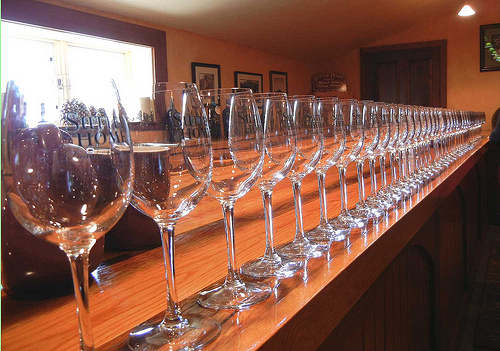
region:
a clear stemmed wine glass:
[4, 72, 127, 344]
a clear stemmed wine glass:
[115, 79, 218, 347]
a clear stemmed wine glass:
[181, 85, 272, 311]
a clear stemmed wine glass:
[223, 86, 300, 281]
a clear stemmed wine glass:
[262, 90, 322, 261]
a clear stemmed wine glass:
[293, 90, 346, 245]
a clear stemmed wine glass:
[318, 94, 368, 232]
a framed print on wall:
[188, 58, 223, 109]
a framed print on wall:
[231, 67, 263, 109]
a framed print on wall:
[266, 69, 289, 101]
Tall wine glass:
[5, 71, 127, 349]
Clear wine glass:
[113, 72, 215, 349]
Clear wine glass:
[189, 76, 267, 336]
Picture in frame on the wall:
[475, 22, 498, 77]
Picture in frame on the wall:
[185, 55, 225, 121]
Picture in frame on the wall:
[230, 70, 265, 109]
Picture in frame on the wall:
[269, 70, 290, 112]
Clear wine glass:
[283, 96, 321, 256]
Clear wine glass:
[362, 98, 382, 237]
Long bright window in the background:
[0, 45, 170, 122]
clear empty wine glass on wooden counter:
[4, 67, 131, 341]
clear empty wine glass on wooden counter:
[131, 88, 206, 340]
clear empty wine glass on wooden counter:
[203, 87, 265, 209]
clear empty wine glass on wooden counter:
[285, 94, 327, 260]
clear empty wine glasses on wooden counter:
[353, 104, 380, 225]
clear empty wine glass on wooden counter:
[395, 103, 419, 200]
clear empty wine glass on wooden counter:
[453, 112, 465, 157]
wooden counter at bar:
[335, 279, 467, 340]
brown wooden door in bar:
[358, 40, 447, 96]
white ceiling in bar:
[186, 9, 391, 31]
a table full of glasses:
[10, 10, 499, 307]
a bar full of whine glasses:
[44, 10, 498, 246]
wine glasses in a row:
[11, 17, 493, 284]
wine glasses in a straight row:
[19, 17, 495, 327]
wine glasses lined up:
[34, 45, 494, 277]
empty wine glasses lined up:
[11, 20, 478, 315]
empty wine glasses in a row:
[39, 17, 484, 303]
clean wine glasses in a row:
[1, 25, 404, 348]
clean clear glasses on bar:
[32, 37, 499, 309]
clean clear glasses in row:
[18, 28, 496, 303]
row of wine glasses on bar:
[129, 103, 463, 201]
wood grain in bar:
[105, 276, 148, 313]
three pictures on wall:
[177, 56, 298, 108]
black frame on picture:
[163, 50, 228, 97]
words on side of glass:
[54, 108, 128, 154]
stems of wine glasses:
[236, 182, 348, 246]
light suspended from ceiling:
[442, 2, 483, 33]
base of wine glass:
[131, 304, 220, 349]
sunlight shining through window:
[35, 32, 169, 119]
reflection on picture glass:
[478, 36, 498, 69]